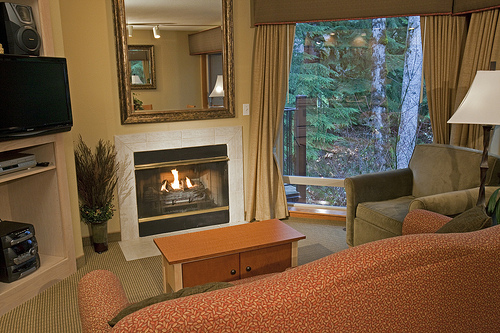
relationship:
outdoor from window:
[282, 18, 426, 210] [249, 4, 477, 211]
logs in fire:
[145, 162, 225, 207] [131, 152, 253, 222]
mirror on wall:
[112, 2, 236, 122] [63, 4, 258, 229]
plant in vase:
[71, 130, 139, 261] [69, 200, 123, 263]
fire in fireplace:
[155, 164, 206, 203] [104, 116, 258, 246]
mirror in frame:
[112, 2, 236, 122] [113, 4, 129, 116]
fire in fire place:
[155, 164, 206, 203] [117, 126, 249, 256]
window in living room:
[282, 17, 433, 212] [6, 7, 480, 330]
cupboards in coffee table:
[178, 245, 306, 275] [112, 211, 341, 293]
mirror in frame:
[123, 15, 232, 125] [116, 56, 132, 107]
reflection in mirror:
[137, 4, 175, 112] [116, 33, 271, 141]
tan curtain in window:
[247, 25, 289, 215] [296, 23, 423, 188]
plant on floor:
[71, 130, 139, 261] [313, 205, 347, 254]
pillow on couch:
[430, 198, 498, 254] [409, 156, 436, 186]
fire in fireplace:
[155, 164, 206, 203] [131, 138, 237, 239]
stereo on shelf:
[3, 215, 42, 282] [29, 244, 78, 295]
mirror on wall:
[123, 15, 232, 125] [28, 1, 255, 242]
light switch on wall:
[242, 103, 250, 114] [63, 4, 258, 229]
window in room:
[282, 17, 433, 212] [3, 1, 496, 331]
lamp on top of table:
[445, 60, 499, 205] [447, 211, 499, 217]